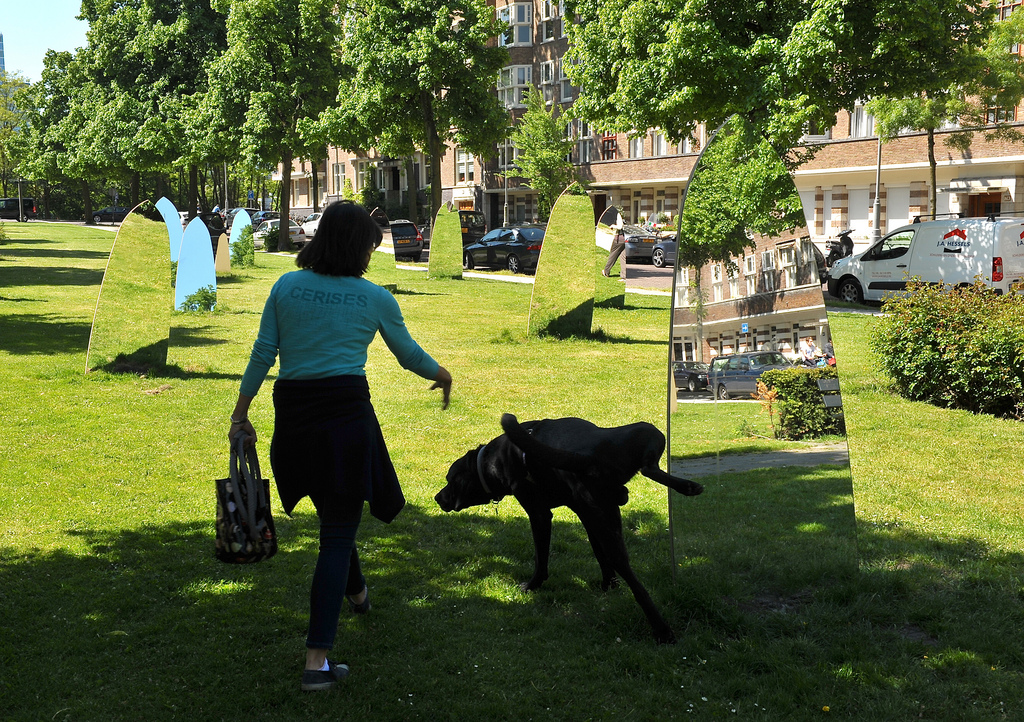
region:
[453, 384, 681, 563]
The balck dog is on the grass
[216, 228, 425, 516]
Woman wearing white shirt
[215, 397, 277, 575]
Woman holding a bag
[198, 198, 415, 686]
Woman walking on grass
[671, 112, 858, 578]
A triangular mirror installed on the ground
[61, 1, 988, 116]
Large trees are in the background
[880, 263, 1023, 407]
Green bush is on the ground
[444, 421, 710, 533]
The dog is taking a leak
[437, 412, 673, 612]
a dog with its leg raised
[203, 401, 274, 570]
a woman holding a bag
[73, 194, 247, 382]
several mirrors stuck in the ground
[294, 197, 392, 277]
a woman with dark hair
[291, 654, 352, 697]
a woman wearing blue shoes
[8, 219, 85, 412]
a field of green grass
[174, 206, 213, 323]
a mirror with the reflection of the sky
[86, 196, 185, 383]
a mirror reflecting the grass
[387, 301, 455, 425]
a woman with her arm stretched out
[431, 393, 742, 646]
The black dog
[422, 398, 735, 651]
A black dog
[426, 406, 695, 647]
The dog is taking a tinkle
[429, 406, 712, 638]
A dog urinating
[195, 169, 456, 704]
The woman carrying a bag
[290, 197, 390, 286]
The hair of the woman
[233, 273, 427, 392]
The blue shirt of the woman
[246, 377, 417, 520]
The black sweater of the woman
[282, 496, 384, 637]
The jeans of the woman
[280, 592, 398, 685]
The shoes of the woman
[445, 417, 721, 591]
a black dog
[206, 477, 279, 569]
a bag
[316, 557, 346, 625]
women wearing pants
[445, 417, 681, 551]
a black dog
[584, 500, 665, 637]
the dogs leg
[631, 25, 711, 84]
green bush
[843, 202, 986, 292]
a white van in the street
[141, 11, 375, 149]
the trees are green and tall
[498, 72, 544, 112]
a window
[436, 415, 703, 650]
a dog peeing on a mirror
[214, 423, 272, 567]
a bag in a woman's hand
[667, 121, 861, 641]
a mirror in a park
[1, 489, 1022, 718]
the shadow of a tree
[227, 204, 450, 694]
a woman walking in a park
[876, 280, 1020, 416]
a bush in a park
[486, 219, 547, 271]
a parked black car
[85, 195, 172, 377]
a mirror in a park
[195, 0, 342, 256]
a tree near the curb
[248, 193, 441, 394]
woman wearing a teal shirt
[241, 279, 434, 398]
shirt has writing on it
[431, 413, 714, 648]
the dog is lifting its hind leg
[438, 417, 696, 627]
the dog is black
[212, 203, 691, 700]
woman and dog walking in the grass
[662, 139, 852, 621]
a reflection in a mirror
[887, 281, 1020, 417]
the bush has green leaves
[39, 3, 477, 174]
the trees have green leaves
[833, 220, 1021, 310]
the van is white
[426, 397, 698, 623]
Dog using the bathroom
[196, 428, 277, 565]
Bag in a woman's hand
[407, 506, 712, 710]
Shadow on the ground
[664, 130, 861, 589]
Mirror on the grass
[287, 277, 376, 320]
Writing on a shirt